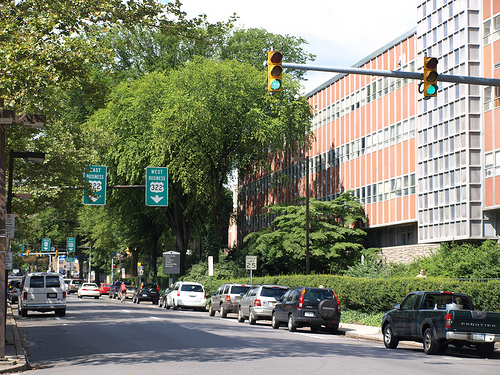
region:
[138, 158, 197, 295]
Green street sign attached to pole.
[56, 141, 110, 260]
Green street sign attached to pole.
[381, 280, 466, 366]
Dark colored truck parked on side of road.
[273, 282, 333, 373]
Black Honda parked on side of road.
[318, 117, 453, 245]
Large building on side of road.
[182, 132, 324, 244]
Large green trees near building.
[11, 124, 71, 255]
Tall street lights on left side of road.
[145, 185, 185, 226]
White arrow on sign.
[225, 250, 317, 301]
White speed limit sign.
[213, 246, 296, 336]
Speed limit is 25.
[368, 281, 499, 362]
Pick up truck parked on side of street.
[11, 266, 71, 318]
Rear of white truck parked on side of street.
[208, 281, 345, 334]
Three cars parked on side of street.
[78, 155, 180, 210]
Green and white traffic signs hanging over street.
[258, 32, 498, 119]
Two traffic lights hanging over street.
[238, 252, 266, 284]
White and black traffic sign on sidewalk.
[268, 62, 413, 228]
Windows on side of building facing street.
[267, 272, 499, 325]
Hedge growing next to sidewalk.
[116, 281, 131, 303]
Person in red riding a bicycle down street.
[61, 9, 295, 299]
Trees growing on sidewalk.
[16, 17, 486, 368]
a city street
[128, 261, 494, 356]
cars are parked along the street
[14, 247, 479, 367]
cars are parked on both sides of the street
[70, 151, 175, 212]
two green street signs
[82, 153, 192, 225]
two street signs hang from a metal pole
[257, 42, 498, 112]
the traffic light is green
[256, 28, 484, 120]
traffic lights hanging from a metal pole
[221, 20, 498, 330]
a building on the side of the road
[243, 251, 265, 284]
a speed limit sign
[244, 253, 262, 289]
the speed limit on this road is 25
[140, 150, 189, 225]
Green sign attached to pole.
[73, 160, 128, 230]
Green sign attached to pole.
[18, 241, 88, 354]
White van parked on side of road.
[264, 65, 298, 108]
Traffic light is green.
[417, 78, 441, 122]
Traffic light is green.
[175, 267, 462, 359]
Cars lined up parked on side of road.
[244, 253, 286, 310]
Sign says 25 mph.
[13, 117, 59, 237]
Street lights on left side of road.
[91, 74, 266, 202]
Tall green trees near building.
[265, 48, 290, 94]
a yellow traffic signal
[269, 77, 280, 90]
a green light on a traffic signal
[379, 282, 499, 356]
a dark colored pick-up truck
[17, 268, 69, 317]
a white colored van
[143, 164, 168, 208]
a green traffic sign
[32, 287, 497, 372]
a road with cars parked on the sides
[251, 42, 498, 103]
two traffic signals on a pole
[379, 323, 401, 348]
a rubber car tire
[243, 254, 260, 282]
a white colored traffic sign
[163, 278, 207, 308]
a white colored vehicle